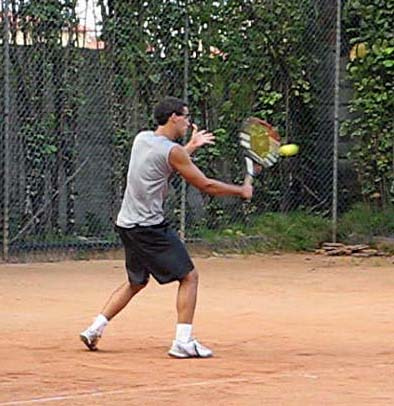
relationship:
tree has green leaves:
[62, 26, 85, 234] [69, 51, 87, 110]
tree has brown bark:
[62, 26, 85, 234] [64, 188, 76, 227]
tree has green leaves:
[47, 35, 67, 237] [44, 120, 58, 157]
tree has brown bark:
[47, 35, 67, 237] [50, 165, 58, 192]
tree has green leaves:
[12, 6, 47, 238] [10, 4, 37, 38]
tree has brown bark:
[12, 6, 47, 238] [14, 67, 26, 97]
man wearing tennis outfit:
[79, 95, 251, 357] [116, 131, 194, 283]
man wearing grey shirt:
[79, 95, 251, 357] [114, 129, 179, 230]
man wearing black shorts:
[79, 95, 251, 357] [118, 224, 194, 285]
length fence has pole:
[308, 7, 381, 240] [330, 0, 344, 246]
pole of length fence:
[330, 0, 344, 246] [308, 7, 381, 240]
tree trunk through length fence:
[63, 122, 78, 172] [3, 4, 115, 261]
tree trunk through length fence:
[46, 168, 61, 218] [3, 4, 115, 261]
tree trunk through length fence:
[27, 163, 40, 210] [3, 4, 115, 261]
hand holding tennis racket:
[237, 182, 252, 199] [237, 115, 278, 205]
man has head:
[76, 95, 254, 361] [144, 92, 194, 142]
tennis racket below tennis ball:
[231, 109, 285, 207] [275, 137, 302, 161]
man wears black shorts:
[76, 95, 254, 361] [118, 224, 194, 285]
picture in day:
[2, 4, 388, 403] [6, 0, 392, 404]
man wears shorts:
[76, 95, 254, 361] [71, 90, 257, 363]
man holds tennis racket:
[76, 95, 254, 361] [231, 109, 285, 207]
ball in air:
[277, 141, 299, 161] [215, 78, 356, 211]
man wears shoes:
[76, 95, 254, 361] [72, 324, 218, 362]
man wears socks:
[76, 95, 254, 361] [89, 313, 195, 338]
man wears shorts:
[76, 95, 254, 361] [112, 224, 197, 291]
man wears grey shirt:
[76, 95, 254, 361] [114, 129, 179, 230]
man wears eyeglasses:
[76, 95, 254, 361] [181, 107, 192, 121]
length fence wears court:
[0, 0, 394, 257] [0, 238, 394, 406]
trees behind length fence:
[6, 5, 379, 237] [0, 0, 394, 257]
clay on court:
[109, 335, 255, 371] [8, 252, 381, 401]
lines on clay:
[5, 372, 325, 401] [1, 246, 379, 400]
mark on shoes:
[176, 343, 201, 355] [166, 335, 215, 360]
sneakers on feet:
[77, 315, 211, 357] [76, 315, 221, 354]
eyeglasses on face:
[176, 110, 192, 121] [172, 106, 189, 136]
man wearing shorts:
[79, 95, 251, 357] [116, 218, 195, 287]